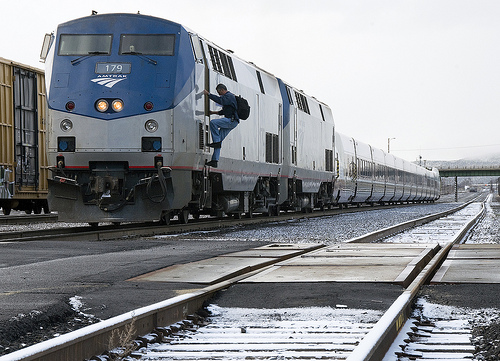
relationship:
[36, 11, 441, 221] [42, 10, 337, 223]
train has a powerful locomotive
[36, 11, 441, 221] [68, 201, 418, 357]
train on railroad tracks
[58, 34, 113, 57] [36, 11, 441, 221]
train window are in front of train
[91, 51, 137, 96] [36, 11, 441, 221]
decal no train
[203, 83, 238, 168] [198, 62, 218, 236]
man climbing a ladder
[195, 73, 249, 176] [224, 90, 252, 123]
man wearing backpack